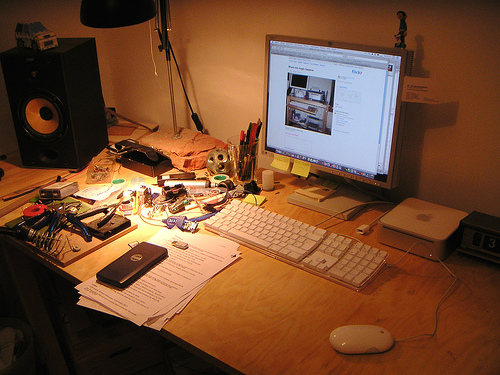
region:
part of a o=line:
[248, 304, 268, 336]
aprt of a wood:
[247, 316, 268, 343]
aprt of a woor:
[253, 323, 278, 351]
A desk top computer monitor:
[262, 32, 414, 220]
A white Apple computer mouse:
[329, 323, 394, 356]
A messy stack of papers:
[73, 225, 243, 332]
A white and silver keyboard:
[202, 196, 391, 294]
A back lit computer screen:
[266, 38, 400, 183]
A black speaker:
[2, 35, 111, 171]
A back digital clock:
[459, 211, 499, 266]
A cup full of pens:
[228, 118, 263, 187]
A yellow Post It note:
[289, 157, 311, 179]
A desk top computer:
[378, 196, 470, 262]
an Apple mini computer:
[380, 188, 473, 268]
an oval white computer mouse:
[321, 241, 459, 366]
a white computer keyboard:
[197, 195, 388, 302]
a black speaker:
[5, 35, 115, 166]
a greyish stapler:
[108, 138, 173, 181]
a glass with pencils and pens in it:
[225, 115, 263, 190]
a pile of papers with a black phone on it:
[67, 220, 243, 336]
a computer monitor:
[256, 28, 404, 188]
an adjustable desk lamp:
[78, 0, 233, 170]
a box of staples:
[38, 180, 84, 204]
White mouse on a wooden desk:
[331, 323, 395, 353]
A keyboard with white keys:
[204, 198, 387, 292]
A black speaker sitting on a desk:
[0, 35, 109, 176]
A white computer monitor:
[256, 29, 406, 219]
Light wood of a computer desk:
[213, 282, 498, 371]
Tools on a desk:
[15, 191, 133, 246]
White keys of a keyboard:
[206, 198, 388, 289]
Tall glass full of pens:
[226, 120, 262, 186]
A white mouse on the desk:
[329, 323, 396, 353]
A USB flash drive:
[173, 238, 188, 249]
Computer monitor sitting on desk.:
[257, 27, 409, 227]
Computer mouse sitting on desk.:
[316, 314, 408, 357]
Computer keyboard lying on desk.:
[206, 187, 393, 294]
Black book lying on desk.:
[96, 243, 172, 292]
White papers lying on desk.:
[135, 225, 247, 331]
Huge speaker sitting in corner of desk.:
[3, 32, 115, 169]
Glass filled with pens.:
[223, 112, 269, 187]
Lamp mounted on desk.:
[78, 0, 193, 140]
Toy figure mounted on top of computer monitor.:
[384, 9, 418, 53]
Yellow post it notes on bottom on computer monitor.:
[268, 153, 317, 180]